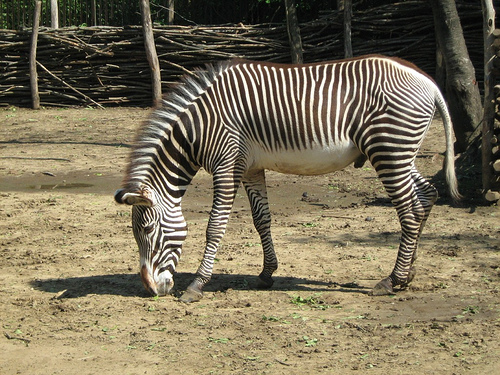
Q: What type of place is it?
A: It is a zoo.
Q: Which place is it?
A: It is a zoo.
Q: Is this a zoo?
A: Yes, it is a zoo.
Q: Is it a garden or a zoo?
A: It is a zoo.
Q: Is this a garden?
A: No, it is a zoo.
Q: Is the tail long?
A: Yes, the tail is long.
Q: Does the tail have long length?
A: Yes, the tail is long.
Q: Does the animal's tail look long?
A: Yes, the tail is long.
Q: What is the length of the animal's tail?
A: The tail is long.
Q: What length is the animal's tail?
A: The tail is long.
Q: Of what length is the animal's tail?
A: The tail is long.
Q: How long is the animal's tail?
A: The tail is long.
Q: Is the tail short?
A: No, the tail is long.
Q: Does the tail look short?
A: No, the tail is long.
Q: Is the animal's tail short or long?
A: The tail is long.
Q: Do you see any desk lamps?
A: No, there are no desk lamps.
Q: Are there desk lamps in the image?
A: No, there are no desk lamps.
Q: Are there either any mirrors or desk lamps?
A: No, there are no desk lamps or mirrors.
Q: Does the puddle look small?
A: Yes, the puddle is small.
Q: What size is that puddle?
A: The puddle is small.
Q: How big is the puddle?
A: The puddle is small.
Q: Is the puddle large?
A: No, the puddle is small.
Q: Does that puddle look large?
A: No, the puddle is small.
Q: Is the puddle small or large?
A: The puddle is small.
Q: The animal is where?
A: The animal is in the zoo.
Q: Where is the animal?
A: The animal is in the zoo.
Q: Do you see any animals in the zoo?
A: Yes, there is an animal in the zoo.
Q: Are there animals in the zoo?
A: Yes, there is an animal in the zoo.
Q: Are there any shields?
A: No, there are no shields.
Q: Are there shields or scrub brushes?
A: No, there are no shields or scrub brushes.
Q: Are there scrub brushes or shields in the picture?
A: No, there are no shields or scrub brushes.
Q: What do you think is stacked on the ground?
A: The sticks are stacked on the ground.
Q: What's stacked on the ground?
A: The sticks are stacked on the ground.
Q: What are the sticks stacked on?
A: The sticks are stacked on the ground.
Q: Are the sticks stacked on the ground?
A: Yes, the sticks are stacked on the ground.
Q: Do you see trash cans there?
A: No, there are no trash cans.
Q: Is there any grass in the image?
A: Yes, there is grass.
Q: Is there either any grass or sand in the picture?
A: Yes, there is grass.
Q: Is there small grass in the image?
A: Yes, there is small grass.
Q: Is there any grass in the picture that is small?
A: Yes, there is grass that is small.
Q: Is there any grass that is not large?
A: Yes, there is small grass.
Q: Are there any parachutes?
A: No, there are no parachutes.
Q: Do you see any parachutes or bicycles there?
A: No, there are no parachutes or bicycles.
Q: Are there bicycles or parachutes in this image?
A: No, there are no parachutes or bicycles.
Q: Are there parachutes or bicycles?
A: No, there are no parachutes or bicycles.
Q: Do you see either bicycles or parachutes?
A: No, there are no parachutes or bicycles.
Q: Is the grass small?
A: Yes, the grass is small.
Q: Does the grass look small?
A: Yes, the grass is small.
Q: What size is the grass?
A: The grass is small.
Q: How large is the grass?
A: The grass is small.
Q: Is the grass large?
A: No, the grass is small.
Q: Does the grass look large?
A: No, the grass is small.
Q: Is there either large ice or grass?
A: No, there is grass but it is small.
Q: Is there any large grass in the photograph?
A: No, there is grass but it is small.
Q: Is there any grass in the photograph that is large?
A: No, there is grass but it is small.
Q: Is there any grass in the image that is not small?
A: No, there is grass but it is small.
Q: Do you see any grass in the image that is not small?
A: No, there is grass but it is small.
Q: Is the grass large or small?
A: The grass is small.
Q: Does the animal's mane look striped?
A: Yes, the mane is striped.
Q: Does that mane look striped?
A: Yes, the mane is striped.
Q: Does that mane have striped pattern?
A: Yes, the mane is striped.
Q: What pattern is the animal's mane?
A: The mane is striped.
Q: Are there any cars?
A: No, there are no cars.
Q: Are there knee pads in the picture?
A: No, there are no knee pads.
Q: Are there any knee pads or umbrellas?
A: No, there are no knee pads or umbrellas.